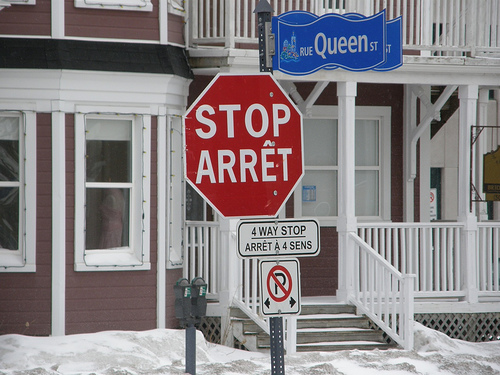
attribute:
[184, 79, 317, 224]
stop sign — large, red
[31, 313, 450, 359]
snow — white, bumpy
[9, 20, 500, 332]
building — brown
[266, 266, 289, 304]
circle — red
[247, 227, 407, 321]
railing — white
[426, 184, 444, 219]
sign — square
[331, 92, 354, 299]
post — white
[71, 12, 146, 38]
bricks — red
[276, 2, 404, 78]
sign — blue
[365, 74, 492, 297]
porch — white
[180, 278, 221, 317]
parking meters — grey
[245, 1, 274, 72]
signpole — metal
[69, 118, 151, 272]
window — white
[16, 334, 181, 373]
ground — snow-covered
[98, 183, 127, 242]
dress — pink